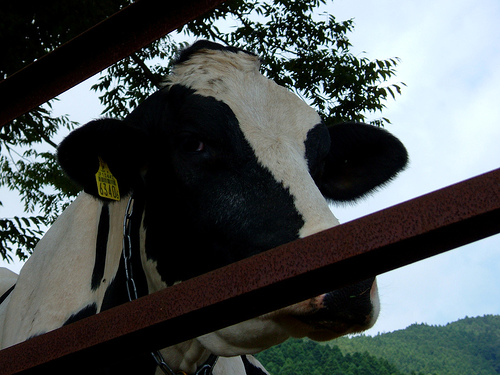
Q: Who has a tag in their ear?
A: A cow.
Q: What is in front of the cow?
A: A fence.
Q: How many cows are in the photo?
A: One.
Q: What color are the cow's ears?
A: Black.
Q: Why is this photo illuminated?
A: Sunlight.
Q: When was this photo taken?
A: Daytime.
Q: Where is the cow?
A: Behind the fence.